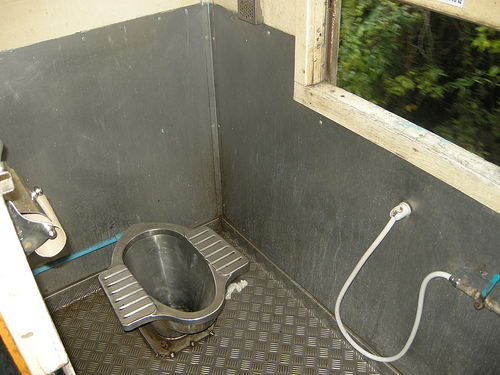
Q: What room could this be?
A: It is a bathroom.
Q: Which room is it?
A: It is a bathroom.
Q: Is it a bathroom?
A: Yes, it is a bathroom.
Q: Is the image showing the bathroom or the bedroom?
A: It is showing the bathroom.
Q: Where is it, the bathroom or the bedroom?
A: It is the bathroom.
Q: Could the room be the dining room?
A: No, it is the bathroom.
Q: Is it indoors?
A: Yes, it is indoors.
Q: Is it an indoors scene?
A: Yes, it is indoors.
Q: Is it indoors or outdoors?
A: It is indoors.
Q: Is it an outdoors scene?
A: No, it is indoors.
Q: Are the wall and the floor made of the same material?
A: Yes, both the wall and the floor are made of metal.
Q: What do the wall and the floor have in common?
A: The material, both the wall and the floor are metallic.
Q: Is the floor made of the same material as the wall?
A: Yes, both the floor and the wall are made of metal.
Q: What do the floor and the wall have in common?
A: The material, both the floor and the wall are metallic.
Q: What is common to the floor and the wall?
A: The material, both the floor and the wall are metallic.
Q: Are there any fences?
A: No, there are no fences.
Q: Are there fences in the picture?
A: No, there are no fences.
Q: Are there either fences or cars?
A: No, there are no fences or cars.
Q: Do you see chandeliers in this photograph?
A: No, there are no chandeliers.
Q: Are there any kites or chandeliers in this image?
A: No, there are no chandeliers or kites.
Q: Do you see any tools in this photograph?
A: No, there are no tools.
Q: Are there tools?
A: No, there are no tools.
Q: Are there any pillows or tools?
A: No, there are no tools or pillows.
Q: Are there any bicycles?
A: No, there are no bicycles.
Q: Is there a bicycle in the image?
A: No, there are no bicycles.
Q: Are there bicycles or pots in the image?
A: No, there are no bicycles or pots.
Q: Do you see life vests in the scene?
A: No, there are no life vests.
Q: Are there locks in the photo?
A: No, there are no locks.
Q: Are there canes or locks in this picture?
A: No, there are no locks or canes.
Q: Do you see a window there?
A: Yes, there is a window.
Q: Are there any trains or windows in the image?
A: Yes, there is a window.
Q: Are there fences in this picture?
A: No, there are no fences.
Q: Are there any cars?
A: No, there are no cars.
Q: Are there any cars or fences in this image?
A: No, there are no cars or fences.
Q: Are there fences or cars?
A: No, there are no cars or fences.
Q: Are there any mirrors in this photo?
A: No, there are no mirrors.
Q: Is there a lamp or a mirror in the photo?
A: No, there are no mirrors or lamps.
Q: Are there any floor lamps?
A: No, there are no floor lamps.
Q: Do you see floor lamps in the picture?
A: No, there are no floor lamps.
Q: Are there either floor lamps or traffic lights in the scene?
A: No, there are no floor lamps or traffic lights.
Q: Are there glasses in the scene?
A: No, there are no glasses.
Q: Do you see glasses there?
A: No, there are no glasses.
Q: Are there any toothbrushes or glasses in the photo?
A: No, there are no glasses or toothbrushes.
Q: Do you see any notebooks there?
A: No, there are no notebooks.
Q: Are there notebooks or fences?
A: No, there are no notebooks or fences.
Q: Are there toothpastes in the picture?
A: No, there are no toothpastes.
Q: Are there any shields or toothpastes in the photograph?
A: No, there are no toothpastes or shields.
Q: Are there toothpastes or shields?
A: No, there are no toothpastes or shields.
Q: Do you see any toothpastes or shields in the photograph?
A: No, there are no toothpastes or shields.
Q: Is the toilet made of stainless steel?
A: Yes, the toilet is made of stainless steel.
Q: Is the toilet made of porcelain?
A: No, the toilet is made of stainless steel.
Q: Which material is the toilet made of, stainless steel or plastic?
A: The toilet is made of stainless steel.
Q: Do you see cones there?
A: No, there are no cones.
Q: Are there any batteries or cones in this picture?
A: No, there are no cones or batteries.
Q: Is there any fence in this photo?
A: No, there are no fences.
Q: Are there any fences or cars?
A: No, there are no fences or cars.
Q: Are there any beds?
A: No, there are no beds.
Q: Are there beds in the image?
A: No, there are no beds.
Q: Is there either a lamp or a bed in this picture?
A: No, there are no beds or lamps.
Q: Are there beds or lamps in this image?
A: No, there are no beds or lamps.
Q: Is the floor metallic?
A: Yes, the floor is metallic.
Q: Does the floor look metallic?
A: Yes, the floor is metallic.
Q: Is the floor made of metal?
A: Yes, the floor is made of metal.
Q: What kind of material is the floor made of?
A: The floor is made of metal.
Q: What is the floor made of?
A: The floor is made of metal.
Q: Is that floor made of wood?
A: No, the floor is made of metal.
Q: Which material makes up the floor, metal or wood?
A: The floor is made of metal.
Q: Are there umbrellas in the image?
A: No, there are no umbrellas.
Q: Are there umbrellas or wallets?
A: No, there are no umbrellas or wallets.